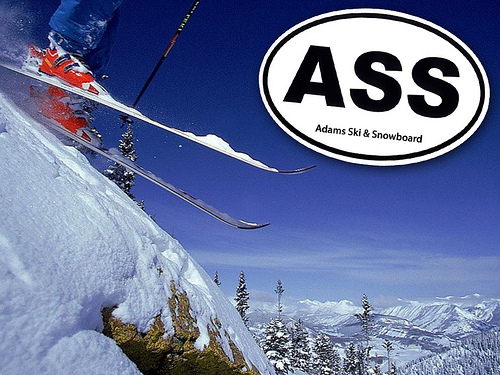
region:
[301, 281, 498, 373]
a beautiful snowy white mountain.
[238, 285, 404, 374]
brown trees covered with snow.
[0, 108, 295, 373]
a snowy mountain hill .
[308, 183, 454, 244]
a dark blue sky.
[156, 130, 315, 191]
a long snowy ski.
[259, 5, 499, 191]
a sign says ass adams ski& snow board.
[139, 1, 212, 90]
a black and brown ski stick.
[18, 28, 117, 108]
a man is wearing a red and black sneaker.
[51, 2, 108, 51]
a man is wearing blue pants.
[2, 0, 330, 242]
a man is skiing down the snowy hill.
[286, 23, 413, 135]
white and black sign says ass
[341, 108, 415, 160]
sign is oval shaped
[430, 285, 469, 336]
snow covered mountains in distance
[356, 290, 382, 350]
tall thin tree in distance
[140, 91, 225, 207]
gray snow covered skis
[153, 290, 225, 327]
brown rock under snow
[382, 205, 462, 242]
clear beautiful blue sky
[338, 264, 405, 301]
white cloud in blue sky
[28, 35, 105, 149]
person in red ski boots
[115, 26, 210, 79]
black and red ski pole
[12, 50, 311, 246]
two long and thin skis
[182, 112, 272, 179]
snow on the ski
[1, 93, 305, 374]
steep slope covered in snow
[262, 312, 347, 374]
dark green trees with snow on the branhes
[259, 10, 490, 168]
black and white logo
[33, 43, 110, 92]
red shoe attached to the ski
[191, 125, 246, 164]
small mound of snow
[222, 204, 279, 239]
end of the ski is turned upward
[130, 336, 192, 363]
bit of ground without snow on it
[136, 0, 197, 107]
thin black ski pole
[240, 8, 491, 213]
An advertisment of Adams Ski and snowboard.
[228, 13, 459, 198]
The picture says ASS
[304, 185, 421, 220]
The sky is void of clouds.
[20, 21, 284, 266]
The skiis are mid-air.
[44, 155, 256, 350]
The mountain is steep.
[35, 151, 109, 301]
Lots of snow on the mountain.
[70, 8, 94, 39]
The skier is wearing blue pants.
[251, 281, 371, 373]
Trees covered the snow.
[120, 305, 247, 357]
Part of the rock is exposed.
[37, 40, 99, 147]
Orange ski boots.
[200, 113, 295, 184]
snow on ski tip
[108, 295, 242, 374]
rock under the snow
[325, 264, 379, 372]
trees below the mountain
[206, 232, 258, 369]
slope of the mountain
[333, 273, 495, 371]
mountains in the distance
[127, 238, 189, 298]
mogal in the snow slope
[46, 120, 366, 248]
skis in the air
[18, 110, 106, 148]
ski boot on ski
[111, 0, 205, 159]
ski pole of skier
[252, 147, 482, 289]
blue of the sky